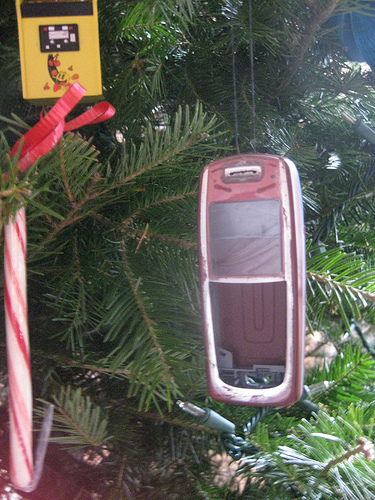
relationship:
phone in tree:
[194, 158, 301, 412] [49, 132, 207, 394]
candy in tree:
[1, 184, 48, 493] [49, 132, 207, 394]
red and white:
[3, 302, 13, 318] [10, 243, 24, 268]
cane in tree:
[8, 199, 30, 485] [49, 132, 207, 394]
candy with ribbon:
[1, 184, 48, 493] [11, 82, 111, 179]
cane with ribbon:
[8, 199, 30, 485] [11, 82, 111, 179]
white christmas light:
[175, 398, 204, 418] [162, 387, 257, 450]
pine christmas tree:
[58, 148, 125, 203] [49, 132, 207, 394]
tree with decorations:
[49, 132, 207, 394] [17, 4, 294, 418]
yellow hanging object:
[25, 50, 50, 90] [16, 0, 104, 101]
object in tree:
[16, 0, 104, 101] [49, 132, 207, 394]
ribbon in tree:
[11, 82, 111, 179] [49, 132, 207, 394]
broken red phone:
[193, 270, 296, 407] [194, 158, 301, 412]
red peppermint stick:
[3, 302, 13, 318] [1, 184, 48, 493]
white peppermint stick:
[10, 243, 24, 268] [1, 184, 48, 493]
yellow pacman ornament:
[25, 50, 50, 90] [16, 0, 104, 101]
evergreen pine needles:
[0, 0, 375, 500] [94, 132, 187, 166]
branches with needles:
[114, 76, 209, 217] [94, 132, 187, 166]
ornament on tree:
[16, 0, 104, 101] [49, 132, 207, 394]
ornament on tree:
[194, 158, 301, 412] [49, 132, 207, 394]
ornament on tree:
[1, 184, 48, 493] [49, 132, 207, 394]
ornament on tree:
[327, 4, 374, 65] [49, 132, 207, 394]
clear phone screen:
[207, 200, 282, 272] [198, 161, 293, 281]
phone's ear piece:
[194, 158, 301, 412] [209, 158, 286, 200]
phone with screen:
[194, 158, 301, 412] [198, 161, 293, 281]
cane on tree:
[8, 199, 30, 485] [49, 132, 207, 394]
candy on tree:
[1, 184, 48, 493] [49, 132, 207, 394]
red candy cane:
[3, 302, 13, 318] [8, 199, 30, 485]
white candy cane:
[10, 243, 24, 268] [8, 199, 30, 485]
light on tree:
[162, 387, 257, 450] [49, 132, 207, 394]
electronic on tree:
[194, 158, 301, 412] [49, 132, 207, 394]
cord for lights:
[231, 404, 272, 468] [162, 387, 257, 450]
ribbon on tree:
[11, 82, 111, 179] [49, 132, 207, 394]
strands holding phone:
[217, 1, 272, 159] [194, 158, 301, 412]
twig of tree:
[125, 99, 199, 173] [49, 132, 207, 394]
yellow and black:
[25, 50, 50, 90] [28, 4, 90, 16]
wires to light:
[225, 413, 293, 468] [176, 398, 237, 433]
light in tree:
[176, 398, 237, 433] [49, 132, 207, 394]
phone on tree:
[194, 158, 301, 412] [49, 132, 207, 394]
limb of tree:
[82, 119, 214, 172] [49, 132, 207, 394]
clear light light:
[175, 398, 204, 418] [176, 398, 237, 433]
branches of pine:
[114, 76, 209, 217] [58, 148, 125, 203]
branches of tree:
[114, 76, 209, 217] [49, 132, 207, 394]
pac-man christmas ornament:
[42, 52, 86, 90] [16, 0, 104, 101]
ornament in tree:
[16, 0, 104, 101] [49, 132, 207, 394]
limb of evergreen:
[36, 132, 210, 240] [58, 121, 188, 209]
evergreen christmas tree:
[58, 121, 188, 209] [49, 132, 207, 394]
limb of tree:
[36, 132, 210, 240] [49, 132, 207, 394]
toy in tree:
[16, 0, 104, 101] [49, 132, 207, 394]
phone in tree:
[197, 153, 305, 406] [49, 132, 207, 394]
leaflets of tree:
[125, 99, 199, 173] [49, 132, 207, 394]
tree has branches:
[49, 132, 207, 394] [114, 76, 209, 217]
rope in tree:
[217, 1, 272, 159] [49, 132, 207, 394]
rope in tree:
[214, 9, 256, 141] [49, 132, 207, 394]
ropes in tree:
[217, 1, 272, 159] [49, 132, 207, 394]